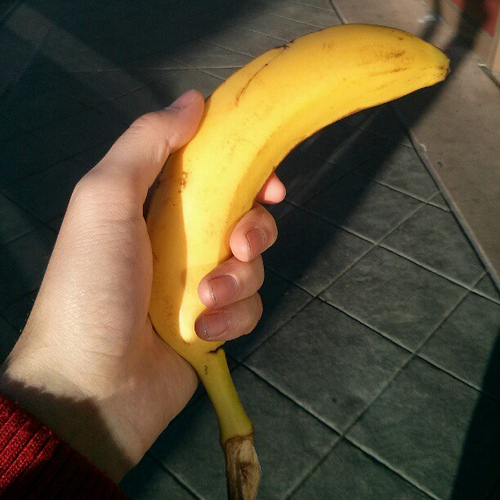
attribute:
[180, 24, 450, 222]
banana — ripe